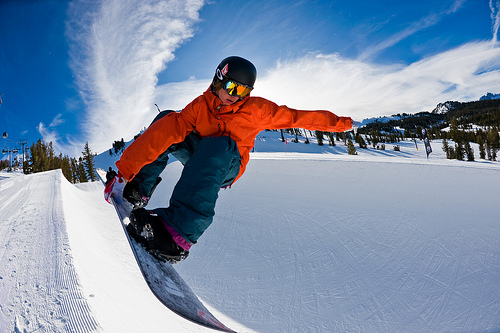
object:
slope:
[86, 166, 280, 331]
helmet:
[213, 54, 258, 90]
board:
[92, 167, 238, 332]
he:
[102, 54, 361, 266]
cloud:
[69, 8, 159, 91]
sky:
[270, 9, 477, 44]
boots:
[122, 206, 189, 268]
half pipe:
[92, 154, 500, 330]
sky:
[3, 3, 195, 89]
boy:
[101, 54, 360, 263]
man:
[102, 55, 360, 266]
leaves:
[453, 142, 465, 159]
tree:
[450, 118, 459, 141]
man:
[102, 55, 364, 266]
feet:
[121, 207, 192, 266]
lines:
[38, 228, 84, 331]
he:
[103, 56, 358, 262]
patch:
[26, 135, 50, 172]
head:
[210, 56, 258, 107]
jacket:
[112, 84, 354, 190]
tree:
[45, 141, 57, 169]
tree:
[80, 141, 96, 177]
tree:
[68, 156, 79, 184]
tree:
[32, 138, 46, 169]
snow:
[2, 132, 495, 331]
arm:
[264, 100, 360, 134]